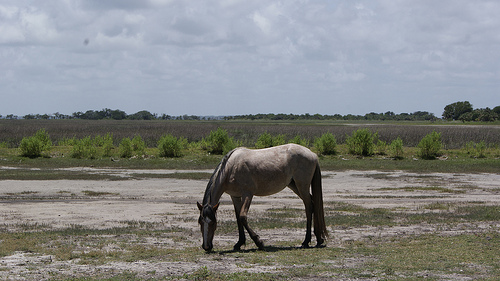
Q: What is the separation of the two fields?
A: A line of bushes.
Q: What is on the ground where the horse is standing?
A: Grass.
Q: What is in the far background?
A: Trees.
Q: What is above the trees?
A: Clouds.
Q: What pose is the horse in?
A: Standing.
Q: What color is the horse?
A: Brown.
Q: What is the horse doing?
A: Eating.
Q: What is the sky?
A: Cloudy.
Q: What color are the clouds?
A: Gray and white.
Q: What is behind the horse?
A: Bushes.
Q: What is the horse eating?
A: Grass.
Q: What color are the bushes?
A: Green.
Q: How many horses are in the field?
A: One.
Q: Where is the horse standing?
A: In a field.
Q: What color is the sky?
A: Blue.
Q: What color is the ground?
A: Tan.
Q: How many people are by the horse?
A: None.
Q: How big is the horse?
A: Not big.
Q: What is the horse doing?
A: Grazing.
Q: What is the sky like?
A: Cloudy.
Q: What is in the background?
A: Trees.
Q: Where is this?
A: Grassland.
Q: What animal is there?
A: Horse.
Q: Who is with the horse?
A: No one.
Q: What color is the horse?
A: Gray.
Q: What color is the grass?
A: Green.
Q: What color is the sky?
A: Blue and white.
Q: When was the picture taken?
A: Daytime.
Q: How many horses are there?
A: One.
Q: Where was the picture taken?
A: In a grassland.